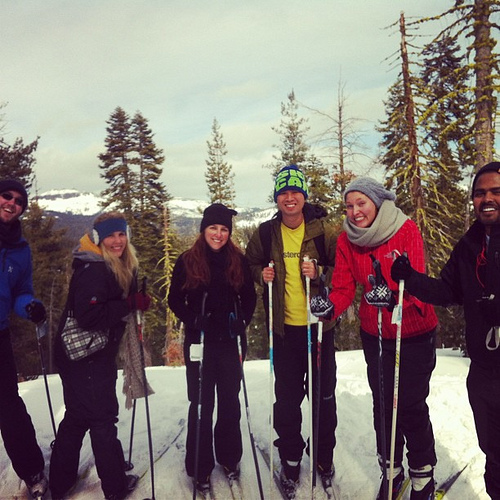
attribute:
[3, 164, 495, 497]
skiers — group, six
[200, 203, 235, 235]
beanie — black 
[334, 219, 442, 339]
sweater — red 